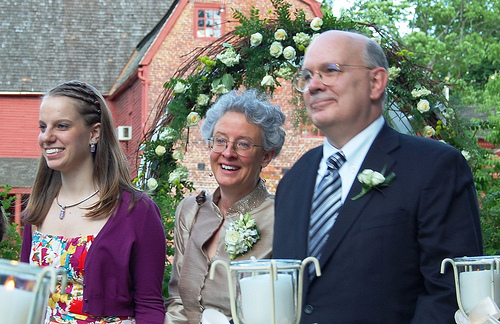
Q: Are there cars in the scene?
A: No, there are no cars.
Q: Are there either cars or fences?
A: No, there are no cars or fences.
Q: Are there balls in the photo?
A: No, there are no balls.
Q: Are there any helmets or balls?
A: No, there are no balls or helmets.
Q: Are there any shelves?
A: No, there are no shelves.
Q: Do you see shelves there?
A: No, there are no shelves.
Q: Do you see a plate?
A: No, there are no plates.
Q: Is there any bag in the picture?
A: No, there are no bags.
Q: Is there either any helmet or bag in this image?
A: No, there are no bags or helmets.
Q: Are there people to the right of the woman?
A: Yes, there is a person to the right of the woman.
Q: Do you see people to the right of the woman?
A: Yes, there is a person to the right of the woman.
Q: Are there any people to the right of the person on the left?
A: Yes, there is a person to the right of the woman.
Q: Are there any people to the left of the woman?
A: No, the person is to the right of the woman.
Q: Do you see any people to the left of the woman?
A: No, the person is to the right of the woman.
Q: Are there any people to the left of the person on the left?
A: No, the person is to the right of the woman.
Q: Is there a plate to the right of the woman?
A: No, there is a person to the right of the woman.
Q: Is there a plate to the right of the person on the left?
A: No, there is a person to the right of the woman.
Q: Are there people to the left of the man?
A: Yes, there is a person to the left of the man.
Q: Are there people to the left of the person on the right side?
A: Yes, there is a person to the left of the man.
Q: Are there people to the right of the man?
A: No, the person is to the left of the man.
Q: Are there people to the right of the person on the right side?
A: No, the person is to the left of the man.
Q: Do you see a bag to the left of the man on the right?
A: No, there is a person to the left of the man.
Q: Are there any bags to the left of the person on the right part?
A: No, there is a person to the left of the man.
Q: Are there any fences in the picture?
A: No, there are no fences.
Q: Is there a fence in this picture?
A: No, there are no fences.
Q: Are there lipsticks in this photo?
A: No, there are no lipsticks.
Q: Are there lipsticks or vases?
A: No, there are no lipsticks or vases.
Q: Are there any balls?
A: No, there are no balls.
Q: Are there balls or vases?
A: No, there are no balls or vases.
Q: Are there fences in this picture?
A: No, there are no fences.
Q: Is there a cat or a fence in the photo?
A: No, there are no fences or cats.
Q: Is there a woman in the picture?
A: Yes, there is a woman.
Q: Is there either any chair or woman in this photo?
A: Yes, there is a woman.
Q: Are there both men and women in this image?
A: Yes, there are both a woman and a man.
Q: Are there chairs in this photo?
A: No, there are no chairs.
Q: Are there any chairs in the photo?
A: No, there are no chairs.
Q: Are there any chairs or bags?
A: No, there are no chairs or bags.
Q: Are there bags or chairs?
A: No, there are no chairs or bags.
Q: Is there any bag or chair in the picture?
A: No, there are no chairs or bags.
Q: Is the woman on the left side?
A: Yes, the woman is on the left of the image.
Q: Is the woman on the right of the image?
A: No, the woman is on the left of the image.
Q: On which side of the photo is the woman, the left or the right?
A: The woman is on the left of the image.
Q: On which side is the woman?
A: The woman is on the left of the image.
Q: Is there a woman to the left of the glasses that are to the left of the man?
A: Yes, there is a woman to the left of the glasses.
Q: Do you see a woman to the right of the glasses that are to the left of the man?
A: No, the woman is to the left of the glasses.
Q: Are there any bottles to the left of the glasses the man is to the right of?
A: No, there is a woman to the left of the glasses.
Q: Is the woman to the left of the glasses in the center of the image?
A: Yes, the woman is to the left of the glasses.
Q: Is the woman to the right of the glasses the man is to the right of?
A: No, the woman is to the left of the glasses.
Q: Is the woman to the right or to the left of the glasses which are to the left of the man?
A: The woman is to the left of the glasses.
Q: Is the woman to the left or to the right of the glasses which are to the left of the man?
A: The woman is to the left of the glasses.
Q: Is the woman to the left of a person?
A: Yes, the woman is to the left of a person.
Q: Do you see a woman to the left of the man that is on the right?
A: Yes, there is a woman to the left of the man.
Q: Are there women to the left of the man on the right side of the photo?
A: Yes, there is a woman to the left of the man.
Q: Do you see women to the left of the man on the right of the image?
A: Yes, there is a woman to the left of the man.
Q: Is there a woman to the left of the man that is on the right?
A: Yes, there is a woman to the left of the man.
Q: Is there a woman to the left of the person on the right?
A: Yes, there is a woman to the left of the man.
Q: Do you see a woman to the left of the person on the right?
A: Yes, there is a woman to the left of the man.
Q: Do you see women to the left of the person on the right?
A: Yes, there is a woman to the left of the man.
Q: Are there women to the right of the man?
A: No, the woman is to the left of the man.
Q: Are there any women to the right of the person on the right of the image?
A: No, the woman is to the left of the man.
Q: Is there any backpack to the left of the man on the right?
A: No, there is a woman to the left of the man.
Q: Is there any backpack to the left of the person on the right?
A: No, there is a woman to the left of the man.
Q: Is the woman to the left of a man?
A: Yes, the woman is to the left of a man.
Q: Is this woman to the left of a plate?
A: No, the woman is to the left of a man.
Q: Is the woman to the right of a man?
A: No, the woman is to the left of a man.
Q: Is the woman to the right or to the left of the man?
A: The woman is to the left of the man.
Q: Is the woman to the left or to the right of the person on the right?
A: The woman is to the left of the man.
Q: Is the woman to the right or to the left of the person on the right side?
A: The woman is to the left of the man.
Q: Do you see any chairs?
A: No, there are no chairs.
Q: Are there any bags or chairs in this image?
A: No, there are no chairs or bags.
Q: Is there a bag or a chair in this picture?
A: No, there are no chairs or bags.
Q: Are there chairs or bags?
A: No, there are no chairs or bags.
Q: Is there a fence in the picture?
A: No, there are no fences.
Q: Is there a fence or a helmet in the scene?
A: No, there are no fences or helmets.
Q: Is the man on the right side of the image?
A: Yes, the man is on the right of the image.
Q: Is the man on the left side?
A: No, the man is on the right of the image.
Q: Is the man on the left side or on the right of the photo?
A: The man is on the right of the image.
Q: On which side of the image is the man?
A: The man is on the right of the image.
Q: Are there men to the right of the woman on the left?
A: Yes, there is a man to the right of the woman.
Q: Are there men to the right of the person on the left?
A: Yes, there is a man to the right of the woman.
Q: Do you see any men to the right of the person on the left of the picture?
A: Yes, there is a man to the right of the woman.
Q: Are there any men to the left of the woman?
A: No, the man is to the right of the woman.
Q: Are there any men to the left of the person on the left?
A: No, the man is to the right of the woman.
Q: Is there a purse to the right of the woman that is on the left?
A: No, there is a man to the right of the woman.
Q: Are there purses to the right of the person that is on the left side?
A: No, there is a man to the right of the woman.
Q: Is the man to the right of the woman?
A: Yes, the man is to the right of the woman.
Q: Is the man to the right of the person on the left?
A: Yes, the man is to the right of the woman.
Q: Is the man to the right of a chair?
A: No, the man is to the right of the woman.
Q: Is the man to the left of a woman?
A: No, the man is to the right of a woman.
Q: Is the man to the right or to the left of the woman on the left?
A: The man is to the right of the woman.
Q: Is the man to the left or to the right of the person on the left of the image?
A: The man is to the right of the woman.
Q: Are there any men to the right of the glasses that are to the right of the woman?
A: Yes, there is a man to the right of the glasses.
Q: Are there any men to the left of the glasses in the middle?
A: No, the man is to the right of the glasses.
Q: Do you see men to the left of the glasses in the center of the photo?
A: No, the man is to the right of the glasses.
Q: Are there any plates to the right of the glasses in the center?
A: No, there is a man to the right of the glasses.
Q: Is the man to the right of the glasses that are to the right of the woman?
A: Yes, the man is to the right of the glasses.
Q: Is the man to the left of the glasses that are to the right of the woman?
A: No, the man is to the right of the glasses.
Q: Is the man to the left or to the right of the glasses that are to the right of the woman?
A: The man is to the right of the glasses.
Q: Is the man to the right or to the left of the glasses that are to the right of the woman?
A: The man is to the right of the glasses.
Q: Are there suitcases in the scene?
A: No, there are no suitcases.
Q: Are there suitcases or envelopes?
A: No, there are no suitcases or envelopes.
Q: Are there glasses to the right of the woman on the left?
A: Yes, there are glasses to the right of the woman.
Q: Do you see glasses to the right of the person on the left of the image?
A: Yes, there are glasses to the right of the woman.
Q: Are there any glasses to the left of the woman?
A: No, the glasses are to the right of the woman.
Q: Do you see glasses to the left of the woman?
A: No, the glasses are to the right of the woman.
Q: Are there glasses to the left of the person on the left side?
A: No, the glasses are to the right of the woman.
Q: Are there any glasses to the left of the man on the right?
A: Yes, there are glasses to the left of the man.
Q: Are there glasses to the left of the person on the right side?
A: Yes, there are glasses to the left of the man.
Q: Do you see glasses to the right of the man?
A: No, the glasses are to the left of the man.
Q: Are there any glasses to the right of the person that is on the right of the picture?
A: No, the glasses are to the left of the man.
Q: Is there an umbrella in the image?
A: No, there are no umbrellas.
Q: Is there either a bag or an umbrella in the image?
A: No, there are no umbrellas or bags.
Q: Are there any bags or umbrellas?
A: No, there are no umbrellas or bags.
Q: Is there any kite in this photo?
A: No, there are no kites.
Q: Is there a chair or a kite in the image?
A: No, there are no kites or chairs.